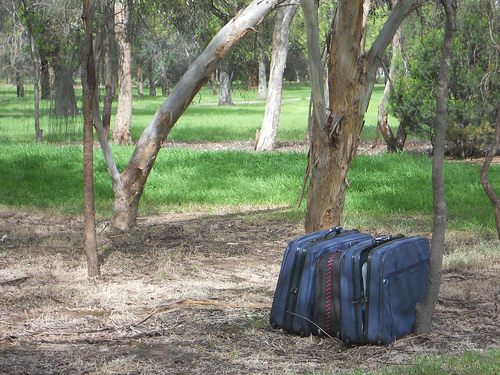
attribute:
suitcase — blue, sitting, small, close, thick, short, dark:
[288, 221, 418, 345]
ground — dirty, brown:
[150, 255, 239, 351]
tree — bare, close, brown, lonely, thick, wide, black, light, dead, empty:
[277, 38, 439, 174]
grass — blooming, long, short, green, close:
[197, 155, 286, 207]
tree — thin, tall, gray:
[393, 1, 465, 337]